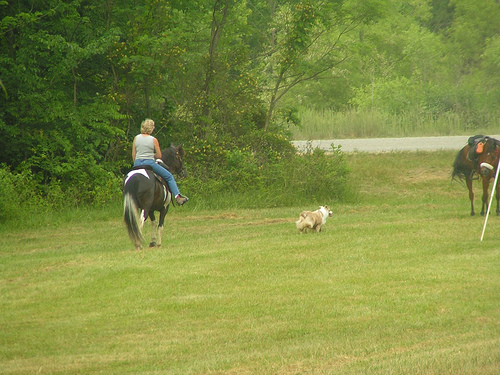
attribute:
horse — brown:
[447, 130, 498, 214]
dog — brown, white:
[292, 190, 336, 251]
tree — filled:
[254, 0, 348, 173]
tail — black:
[452, 143, 473, 172]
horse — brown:
[441, 129, 498, 220]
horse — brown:
[453, 135, 499, 219]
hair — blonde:
[139, 118, 153, 133]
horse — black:
[119, 170, 176, 250]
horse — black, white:
[109, 147, 216, 248]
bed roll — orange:
[473, 135, 489, 158]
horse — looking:
[425, 138, 498, 215]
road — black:
[284, 133, 499, 153]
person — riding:
[127, 115, 191, 209]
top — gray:
[127, 130, 159, 160]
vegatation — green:
[12, 142, 364, 232]